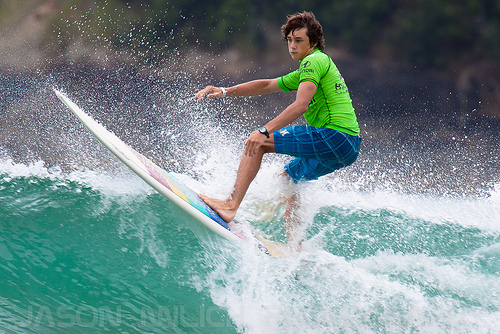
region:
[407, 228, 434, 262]
part of a wave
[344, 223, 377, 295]
part of a lake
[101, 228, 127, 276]
edge of a wave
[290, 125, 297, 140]
part of a short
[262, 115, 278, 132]
part of an arm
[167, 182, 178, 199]
edge of a board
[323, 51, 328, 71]
part of a shirt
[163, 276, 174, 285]
part of a lake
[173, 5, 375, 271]
surfer leaning in towards board tip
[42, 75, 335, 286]
surf board in water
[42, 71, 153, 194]
white surf board tip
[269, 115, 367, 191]
men's blue surf shorts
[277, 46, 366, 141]
neon green sports shirt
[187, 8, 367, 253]
teen male with brown hair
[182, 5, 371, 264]
male surfer on board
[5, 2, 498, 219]
splash droplets atop ocean wave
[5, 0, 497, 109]
green trees in distance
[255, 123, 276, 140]
wristwatch on left wrist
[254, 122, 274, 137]
a person wearing a watch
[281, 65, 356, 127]
man wearing a green shirt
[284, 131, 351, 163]
blue shorts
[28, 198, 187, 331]
the water is blue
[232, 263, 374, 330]
the splash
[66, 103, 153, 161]
a surfboard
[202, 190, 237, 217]
the mans foot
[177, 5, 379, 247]
the man is surfing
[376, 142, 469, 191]
splash of water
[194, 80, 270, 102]
the mans arm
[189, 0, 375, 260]
person wearing a watch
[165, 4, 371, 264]
person wearing a green shirt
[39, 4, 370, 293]
person is surfing on his surfboard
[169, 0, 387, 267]
person is wearing waist band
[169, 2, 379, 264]
person is wearing blue shorts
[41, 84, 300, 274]
a plain old surf board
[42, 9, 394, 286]
person is riding a wave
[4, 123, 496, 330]
wave of an ocean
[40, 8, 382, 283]
person is trying to ride the wave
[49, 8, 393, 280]
person is trying to overcome wave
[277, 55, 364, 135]
green shirt of the surfer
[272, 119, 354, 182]
blue board shorts of surfer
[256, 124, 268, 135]
watch on surfer's wrist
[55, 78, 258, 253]
white surfboard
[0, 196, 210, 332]
swell of the wave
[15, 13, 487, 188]
white spray coming off wave and surfboard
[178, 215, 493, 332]
path of surfboard in wave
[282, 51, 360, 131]
black stitiching on green shirt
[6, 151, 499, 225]
white foam on top of wave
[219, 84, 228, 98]
white band on surfer's wrist